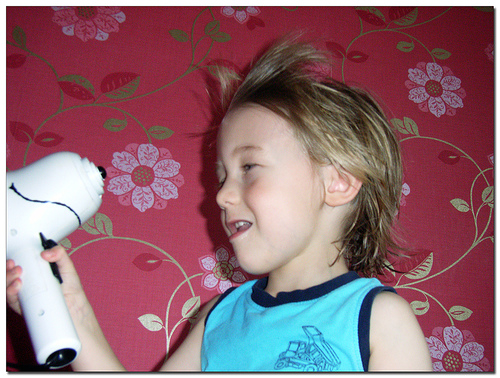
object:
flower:
[101, 135, 188, 214]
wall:
[7, 7, 491, 150]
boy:
[42, 29, 434, 376]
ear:
[322, 151, 367, 209]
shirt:
[199, 262, 396, 372]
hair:
[201, 29, 412, 283]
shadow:
[4, 290, 219, 377]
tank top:
[199, 268, 408, 376]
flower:
[104, 140, 183, 214]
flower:
[401, 58, 465, 120]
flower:
[419, 322, 492, 375]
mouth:
[221, 217, 253, 241]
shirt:
[195, 272, 401, 377]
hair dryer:
[4, 144, 107, 370]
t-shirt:
[201, 269, 401, 373]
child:
[11, 34, 434, 375]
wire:
[8, 354, 63, 373]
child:
[0, 20, 440, 375]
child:
[0, 32, 435, 373]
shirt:
[196, 269, 392, 371]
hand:
[0, 247, 88, 328]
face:
[215, 104, 309, 274]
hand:
[7, 242, 84, 314]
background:
[13, 9, 496, 365]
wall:
[6, 8, 494, 352]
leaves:
[51, 66, 154, 106]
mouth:
[219, 215, 260, 241]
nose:
[209, 181, 242, 210]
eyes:
[215, 155, 267, 188]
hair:
[203, 35, 426, 278]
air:
[87, 115, 192, 192]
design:
[272, 323, 342, 371]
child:
[0, 28, 426, 378]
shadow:
[8, 313, 54, 376]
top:
[195, 275, 387, 373]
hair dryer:
[2, 150, 119, 372]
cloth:
[2, 0, 498, 373]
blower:
[7, 151, 111, 368]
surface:
[10, 7, 488, 375]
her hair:
[191, 27, 414, 300]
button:
[40, 236, 60, 252]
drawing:
[271, 324, 340, 373]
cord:
[40, 352, 74, 370]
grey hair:
[196, 36, 410, 273]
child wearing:
[188, 272, 385, 369]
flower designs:
[43, 7, 133, 43]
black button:
[40, 229, 65, 284]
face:
[215, 105, 322, 275]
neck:
[250, 242, 371, 301]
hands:
[3, 230, 92, 312]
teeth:
[233, 220, 247, 229]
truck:
[273, 325, 344, 372]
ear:
[321, 157, 365, 208]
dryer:
[6, 149, 108, 366]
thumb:
[38, 243, 71, 265]